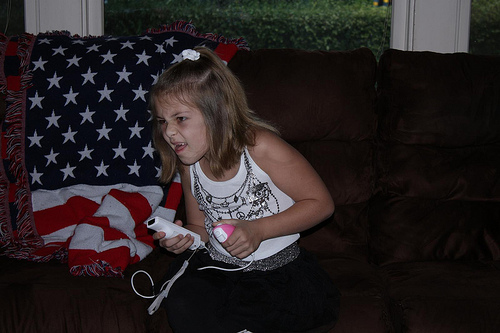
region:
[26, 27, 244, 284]
AMERICAN FLAG THROW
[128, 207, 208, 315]
WII REMOTE CONTROL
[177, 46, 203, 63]
WHITE PONYTAIL HOLDER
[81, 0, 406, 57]
HEDGES OUTSIDE OF THE WINDOW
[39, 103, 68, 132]
A WHITE STAR ON THE FLAG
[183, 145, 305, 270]
GIRLS WHITE TANK TOP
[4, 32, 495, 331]
BROWN SOFA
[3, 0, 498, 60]
WINDOW OVERLOOKING THE HEDGES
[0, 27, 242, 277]
RED WHITE AND BLUE AMERICAN FLAG DRAPED ON THE SOFA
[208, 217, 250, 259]
PINK WII CONTROLLER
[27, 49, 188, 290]
American flag draped below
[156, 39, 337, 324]
little girl playing game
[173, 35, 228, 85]
white hair band holding hair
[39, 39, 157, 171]
white stars group together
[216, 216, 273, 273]
pink wii remote for wii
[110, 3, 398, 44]
window to shoe background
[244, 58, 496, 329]
black couch in front of window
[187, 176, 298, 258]
graphic tank with necklaces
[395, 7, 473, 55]
white frame of window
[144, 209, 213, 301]
white wii remote for wii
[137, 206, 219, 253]
the console is wii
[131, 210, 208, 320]
the wii is white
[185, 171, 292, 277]
the shirt is white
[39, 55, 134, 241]
the flag is USA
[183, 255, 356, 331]
the bottoms is black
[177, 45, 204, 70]
the hair accessory is white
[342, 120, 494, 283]
the couch is brown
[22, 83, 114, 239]
the flag is white, red and blue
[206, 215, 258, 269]
the wii is pink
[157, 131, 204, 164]
the girl is missing toot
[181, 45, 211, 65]
Band is white in color.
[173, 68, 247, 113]
Hair is blonde.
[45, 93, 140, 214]
Flag design is over the sofa.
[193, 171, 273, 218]
Girls top is white in color.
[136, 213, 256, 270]
Child is holding the remote.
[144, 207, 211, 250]
Remote is white in color.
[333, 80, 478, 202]
Sofa is black in color.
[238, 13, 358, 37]
Leaves are green in color.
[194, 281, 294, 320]
Pant is black in color.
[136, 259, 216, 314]
Wire is white in color.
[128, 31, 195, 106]
Stars on an American flag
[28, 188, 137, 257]
Stripes on an American flag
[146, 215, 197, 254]
Wii remote in a girl's hand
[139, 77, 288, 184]
Little girl's face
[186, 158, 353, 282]
Shirt on a little girl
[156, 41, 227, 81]
White hair bow in a girls' hair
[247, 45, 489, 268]
Brown couch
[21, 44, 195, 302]
Flag blanket on a couch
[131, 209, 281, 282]
Two Wii remotes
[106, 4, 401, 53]
Window behind a couch